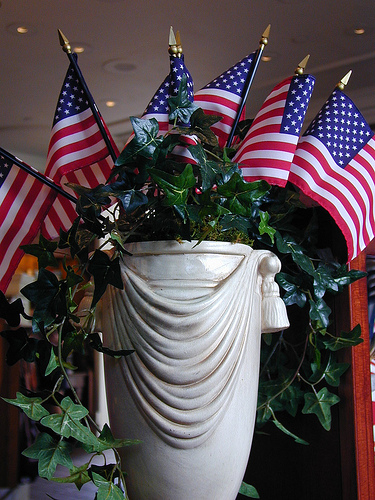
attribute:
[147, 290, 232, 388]
planter — white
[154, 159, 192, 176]
plant — green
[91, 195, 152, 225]
leaf — part, edge, green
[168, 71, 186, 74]
flag — american, plant, six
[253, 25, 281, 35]
pole — gold, small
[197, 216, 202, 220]
twig — part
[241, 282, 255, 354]
vase — edge, white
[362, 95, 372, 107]
door — edge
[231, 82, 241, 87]
stars — white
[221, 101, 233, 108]
stripes — red, white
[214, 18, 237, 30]
ceiling — white